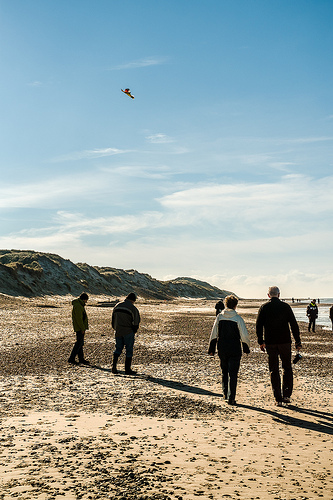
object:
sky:
[0, 3, 333, 301]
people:
[207, 293, 251, 406]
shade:
[133, 369, 223, 397]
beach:
[0, 316, 331, 498]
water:
[296, 296, 331, 321]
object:
[118, 83, 138, 101]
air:
[0, 1, 332, 260]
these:
[111, 291, 142, 376]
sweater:
[255, 300, 301, 350]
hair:
[267, 285, 281, 300]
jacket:
[111, 299, 142, 337]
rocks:
[155, 457, 173, 471]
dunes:
[0, 249, 238, 299]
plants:
[0, 250, 41, 258]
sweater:
[204, 307, 250, 358]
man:
[111, 290, 142, 375]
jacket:
[70, 297, 90, 334]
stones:
[94, 461, 184, 499]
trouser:
[265, 340, 294, 406]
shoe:
[79, 356, 91, 370]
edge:
[234, 401, 261, 415]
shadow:
[234, 400, 333, 438]